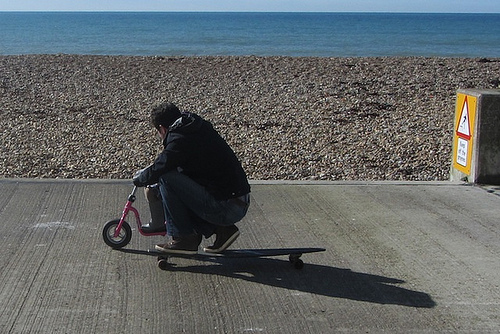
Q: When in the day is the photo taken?
A: Daytime.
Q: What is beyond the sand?
A: Water.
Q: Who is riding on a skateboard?
A: The man.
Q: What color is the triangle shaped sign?
A: White and red.